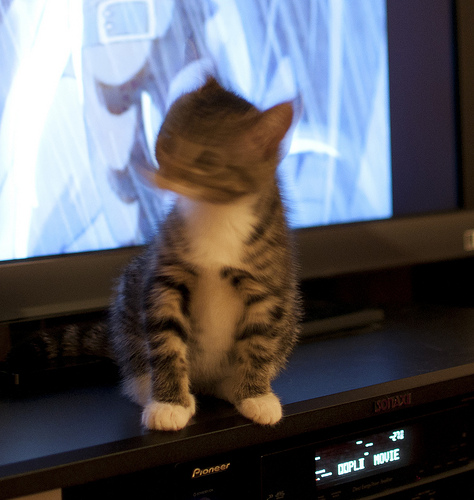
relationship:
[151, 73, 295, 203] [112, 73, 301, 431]
face of kitten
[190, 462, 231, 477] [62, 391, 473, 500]
brand of vcr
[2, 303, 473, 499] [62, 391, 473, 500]
table holding vcr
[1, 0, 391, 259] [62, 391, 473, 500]
movie being shown on vcr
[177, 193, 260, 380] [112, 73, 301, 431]
belly of kitten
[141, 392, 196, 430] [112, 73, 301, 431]
paw of kitten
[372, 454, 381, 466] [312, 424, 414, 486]
letter on display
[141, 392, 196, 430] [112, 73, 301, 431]
paw on kitten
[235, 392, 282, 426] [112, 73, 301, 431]
paw on kitten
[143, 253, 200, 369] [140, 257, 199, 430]
stripes on leg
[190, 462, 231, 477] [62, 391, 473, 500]
brand on vcr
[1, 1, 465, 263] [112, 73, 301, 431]
tv screen behind kitten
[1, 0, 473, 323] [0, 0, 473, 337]
encasing on television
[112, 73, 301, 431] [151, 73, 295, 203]
kitten shaking face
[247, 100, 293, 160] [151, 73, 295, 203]
ear on face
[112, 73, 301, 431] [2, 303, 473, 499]
kitten on table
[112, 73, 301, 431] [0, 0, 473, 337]
kitten in front of television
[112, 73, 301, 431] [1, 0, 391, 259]
kitten in front of movie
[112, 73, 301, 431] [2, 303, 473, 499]
kitten on top of table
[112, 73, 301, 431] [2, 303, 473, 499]
kitten sitting on table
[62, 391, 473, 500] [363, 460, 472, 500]
vcr on shelf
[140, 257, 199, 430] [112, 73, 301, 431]
leg of kitten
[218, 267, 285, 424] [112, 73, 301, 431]
leg of kitten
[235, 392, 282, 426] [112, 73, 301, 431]
paw of kitten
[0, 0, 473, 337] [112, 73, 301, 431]
television behind kitten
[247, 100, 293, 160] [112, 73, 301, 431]
ear of kitten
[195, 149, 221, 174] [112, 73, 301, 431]
eye of kitten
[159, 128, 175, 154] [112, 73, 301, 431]
eye of kitten